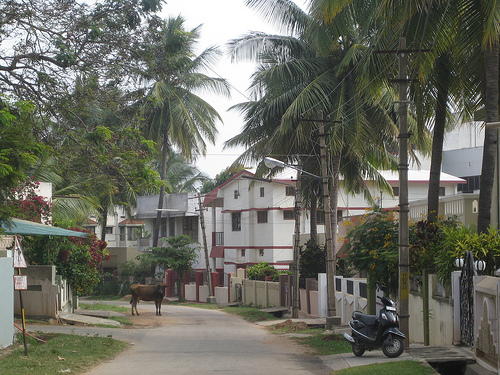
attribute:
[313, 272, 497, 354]
fence — decorative, black, metal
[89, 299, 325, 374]
street — narrow, curved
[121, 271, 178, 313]
cow — brown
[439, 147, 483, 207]
building — tall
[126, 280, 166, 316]
cow — brown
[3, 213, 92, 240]
awning — green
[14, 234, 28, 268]
sign — triangular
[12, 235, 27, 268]
sign — white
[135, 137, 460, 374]
house — white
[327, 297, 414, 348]
bike — motorized, in drive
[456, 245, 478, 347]
gate — black, metal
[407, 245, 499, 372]
wall — stone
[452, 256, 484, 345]
gate — to home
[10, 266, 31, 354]
pole — yellow and black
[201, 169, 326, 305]
building — white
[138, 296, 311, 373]
road — for vehicle, for travel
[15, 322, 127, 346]
street — side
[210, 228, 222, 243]
railing — black , balcony railing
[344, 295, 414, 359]
scooter — parked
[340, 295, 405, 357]
scooter — black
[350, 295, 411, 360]
motorcyle — black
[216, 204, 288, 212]
trim — red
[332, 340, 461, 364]
pad — concrete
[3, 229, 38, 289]
sign — triangular